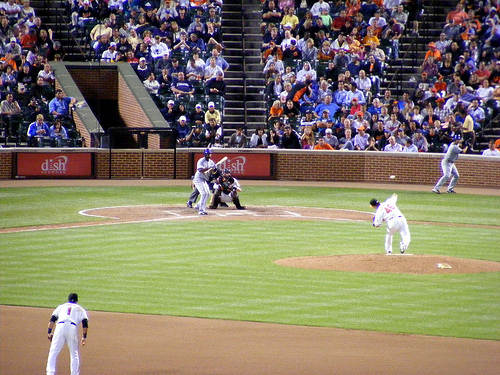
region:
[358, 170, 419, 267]
a pitcher pitching the ball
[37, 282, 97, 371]
baseball player number 1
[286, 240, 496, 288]
the pitchers mound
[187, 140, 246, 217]
a batter and catcher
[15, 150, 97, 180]
red advertisement sign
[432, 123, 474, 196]
a baseball player getting ready to bat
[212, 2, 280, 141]
a row of stairs going up the stadium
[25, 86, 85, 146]
three people wearing blue shirts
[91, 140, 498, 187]
a short wall made of bricks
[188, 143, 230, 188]
batter wearing a blue helmet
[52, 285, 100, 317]
Person wearing black hat.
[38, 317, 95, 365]
Person wearing white pants.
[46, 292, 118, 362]
Person wearing white shirt.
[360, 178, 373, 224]
Person wearing black hat.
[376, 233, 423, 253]
Person wearing white pants.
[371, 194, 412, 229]
Person wearing white shirt.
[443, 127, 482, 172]
Person wearing blue helmet.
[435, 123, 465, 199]
Person wearing gray shirt.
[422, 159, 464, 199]
Person wearing gray pants.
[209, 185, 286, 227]
Catcher has black shin guards on.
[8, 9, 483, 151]
spectator's watching baseball game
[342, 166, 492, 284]
player pitches baseball to batter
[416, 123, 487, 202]
player get's ready to catch ball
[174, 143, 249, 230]
batter, umpire, and referee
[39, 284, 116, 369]
player in white uniform with red number one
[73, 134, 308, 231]
player at home plate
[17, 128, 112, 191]
red advertisement for dish network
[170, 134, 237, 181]
man wearing blue helmet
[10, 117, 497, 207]
brick barricade protecting spectators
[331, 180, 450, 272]
man on pitcher's mound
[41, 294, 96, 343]
1 on a jersey.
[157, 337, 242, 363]
Grass in the outfield.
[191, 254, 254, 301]
The grass is green.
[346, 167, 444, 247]
Pitcher threw the ball.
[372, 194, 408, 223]
46 on the pitcher's jersey.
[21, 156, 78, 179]
Dish logo on a sign.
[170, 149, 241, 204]
Batter behind home plate.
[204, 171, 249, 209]
Catcher behind the batter.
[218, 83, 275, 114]
Steps in the stadium.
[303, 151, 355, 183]
The wall is brick.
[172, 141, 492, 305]
man pitching ball to batter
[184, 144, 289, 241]
batter wearing blue helmet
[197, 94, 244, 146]
person with yellow shirt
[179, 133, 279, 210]
catcher behind home plate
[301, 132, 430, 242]
brick wall around baseball field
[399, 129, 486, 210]
batter on deck swinging bat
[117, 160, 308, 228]
white chalk outline of home plate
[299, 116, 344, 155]
person with orange shirt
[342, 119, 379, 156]
person with orange cap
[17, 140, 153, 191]
red sign with white writing